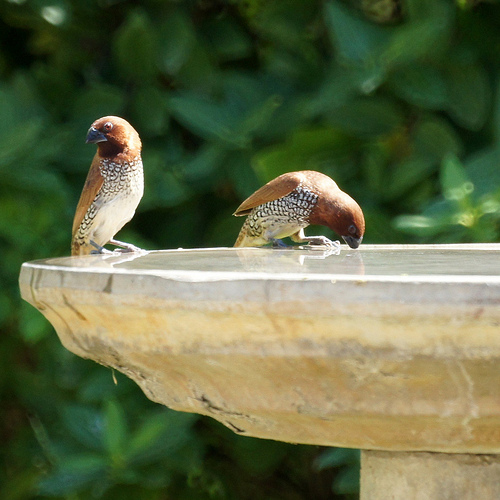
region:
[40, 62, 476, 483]
Two birds drinking water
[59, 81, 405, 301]
Two birds perched on a fountain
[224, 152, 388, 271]
The bird is drinking water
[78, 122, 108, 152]
The bird has a small beak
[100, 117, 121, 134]
The bird's eye is open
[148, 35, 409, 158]
Green leaves behind the birds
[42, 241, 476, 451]
A stone water fountain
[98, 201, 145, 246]
The bird's breast is white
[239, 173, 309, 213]
The bird's wings are brown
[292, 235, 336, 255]
The bird's feet are on the fountain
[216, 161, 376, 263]
brown bird drinking out of the bird bath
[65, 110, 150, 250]
a brown bird looking to its right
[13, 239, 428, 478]
beige stone bird bath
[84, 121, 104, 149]
black bird beak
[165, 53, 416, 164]
green leaves out of focus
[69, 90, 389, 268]
two birds sitting on a bird bath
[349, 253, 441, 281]
water in a bird bath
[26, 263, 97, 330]
water running off the side of the bird bath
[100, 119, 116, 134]
small brown bird eye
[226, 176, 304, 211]
brown wing on bird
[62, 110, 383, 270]
There are two birds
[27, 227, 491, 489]
The fountain is stone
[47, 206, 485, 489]
The fountain is tan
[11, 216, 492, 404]
The fountain is filled with water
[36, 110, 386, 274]
Two birds on the fountain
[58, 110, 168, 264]
The bird is brown and white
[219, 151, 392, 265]
Bird drinking water from the fountain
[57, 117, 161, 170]
Bird has a black beak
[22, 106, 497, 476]
Green bushes behind the fountain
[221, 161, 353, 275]
The bird has brown and white spots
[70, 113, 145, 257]
A bird standing on a bird bath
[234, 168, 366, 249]
A bird drinking from a bird bath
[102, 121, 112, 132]
A bird's left eye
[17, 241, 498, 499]
A stone birdbath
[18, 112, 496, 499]
Two birds standing on a birdbath ledge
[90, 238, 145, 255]
a bird's legs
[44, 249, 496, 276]
Water in a birdbath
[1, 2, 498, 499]
Leaves of some green plants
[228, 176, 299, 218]
A bird's right wing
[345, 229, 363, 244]
The drinking bird's beak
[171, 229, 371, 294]
water in the bird bath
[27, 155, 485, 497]
a stone birdbath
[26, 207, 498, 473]
bowl of water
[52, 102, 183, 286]
a bird sitting on the edge of the birdbath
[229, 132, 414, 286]
a bird drinking water from the bath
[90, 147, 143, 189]
a spotted bird chest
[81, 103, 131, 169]
a brown birds head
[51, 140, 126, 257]
brown wings on a bird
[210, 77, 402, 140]
green bushes behind the bird bath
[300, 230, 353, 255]
bird foot